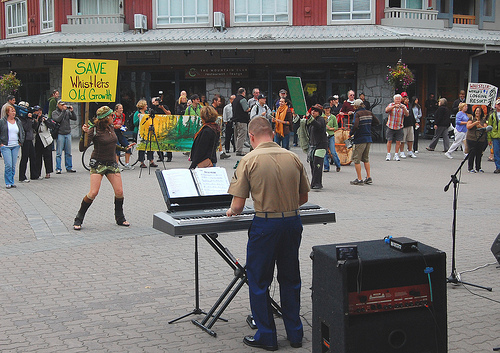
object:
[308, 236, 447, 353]
amp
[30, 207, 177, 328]
sidewalk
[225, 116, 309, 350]
man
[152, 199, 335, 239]
keyboard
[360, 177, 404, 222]
ground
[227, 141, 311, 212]
shirt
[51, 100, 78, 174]
man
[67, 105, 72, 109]
camera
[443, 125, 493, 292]
mic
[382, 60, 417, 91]
flower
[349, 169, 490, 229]
road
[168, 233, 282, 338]
stand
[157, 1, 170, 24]
window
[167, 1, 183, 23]
window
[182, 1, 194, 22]
window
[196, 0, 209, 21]
window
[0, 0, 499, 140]
building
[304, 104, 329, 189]
woman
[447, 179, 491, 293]
stand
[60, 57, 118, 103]
board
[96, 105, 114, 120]
cap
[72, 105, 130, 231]
girl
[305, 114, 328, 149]
shirt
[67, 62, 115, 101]
writing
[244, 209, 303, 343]
pants